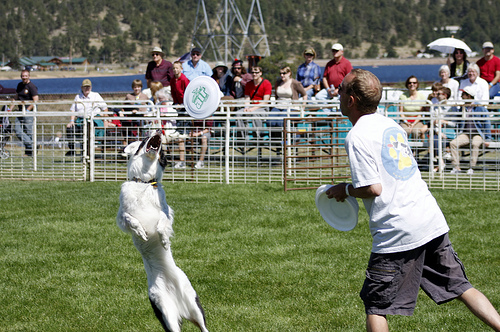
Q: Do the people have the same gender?
A: No, they are both male and female.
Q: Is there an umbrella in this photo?
A: Yes, there is an umbrella.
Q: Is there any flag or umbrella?
A: Yes, there is an umbrella.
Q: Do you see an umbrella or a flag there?
A: Yes, there is an umbrella.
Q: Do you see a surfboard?
A: No, there are no surfboards.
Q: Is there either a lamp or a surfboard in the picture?
A: No, there are no surfboards or lamps.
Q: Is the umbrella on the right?
A: Yes, the umbrella is on the right of the image.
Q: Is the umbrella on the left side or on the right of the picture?
A: The umbrella is on the right of the image.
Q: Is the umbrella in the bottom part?
A: No, the umbrella is in the top of the image.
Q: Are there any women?
A: Yes, there is a woman.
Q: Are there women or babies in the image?
A: Yes, there is a woman.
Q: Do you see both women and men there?
A: Yes, there are both a woman and a man.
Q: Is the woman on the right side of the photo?
A: Yes, the woman is on the right of the image.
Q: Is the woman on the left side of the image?
A: No, the woman is on the right of the image.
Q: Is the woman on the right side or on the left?
A: The woman is on the right of the image.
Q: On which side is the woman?
A: The woman is on the right of the image.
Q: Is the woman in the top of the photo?
A: Yes, the woman is in the top of the image.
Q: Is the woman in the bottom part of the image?
A: No, the woman is in the top of the image.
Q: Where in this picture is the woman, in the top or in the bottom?
A: The woman is in the top of the image.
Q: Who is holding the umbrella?
A: The woman is holding the umbrella.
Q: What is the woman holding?
A: The woman is holding the umbrella.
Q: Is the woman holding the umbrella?
A: Yes, the woman is holding the umbrella.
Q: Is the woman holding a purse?
A: No, the woman is holding the umbrella.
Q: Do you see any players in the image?
A: No, there are no players.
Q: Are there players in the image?
A: No, there are no players.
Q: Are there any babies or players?
A: No, there are no players or babies.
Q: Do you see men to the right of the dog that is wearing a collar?
A: Yes, there is a man to the right of the dog.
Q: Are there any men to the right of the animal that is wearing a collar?
A: Yes, there is a man to the right of the dog.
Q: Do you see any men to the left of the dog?
A: No, the man is to the right of the dog.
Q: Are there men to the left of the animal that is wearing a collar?
A: No, the man is to the right of the dog.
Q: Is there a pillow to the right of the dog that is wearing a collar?
A: No, there is a man to the right of the dog.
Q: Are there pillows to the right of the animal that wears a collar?
A: No, there is a man to the right of the dog.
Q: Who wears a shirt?
A: The man wears a shirt.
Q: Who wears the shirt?
A: The man wears a shirt.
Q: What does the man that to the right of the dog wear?
A: The man wears a shirt.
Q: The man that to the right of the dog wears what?
A: The man wears a shirt.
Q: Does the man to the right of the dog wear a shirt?
A: Yes, the man wears a shirt.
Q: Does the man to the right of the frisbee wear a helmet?
A: No, the man wears a shirt.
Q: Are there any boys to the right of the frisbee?
A: No, there is a man to the right of the frisbee.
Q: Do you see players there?
A: No, there are no players.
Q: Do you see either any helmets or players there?
A: No, there are no players or helmets.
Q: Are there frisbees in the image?
A: Yes, there is a frisbee.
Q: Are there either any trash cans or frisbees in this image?
A: Yes, there is a frisbee.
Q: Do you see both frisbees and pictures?
A: No, there is a frisbee but no pictures.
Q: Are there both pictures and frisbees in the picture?
A: No, there is a frisbee but no pictures.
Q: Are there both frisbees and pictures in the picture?
A: No, there is a frisbee but no pictures.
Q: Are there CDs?
A: No, there are no cds.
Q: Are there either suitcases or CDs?
A: No, there are no CDs or suitcases.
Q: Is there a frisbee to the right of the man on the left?
A: Yes, there is a frisbee to the right of the man.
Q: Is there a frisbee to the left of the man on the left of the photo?
A: No, the frisbee is to the right of the man.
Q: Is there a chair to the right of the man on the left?
A: No, there is a frisbee to the right of the man.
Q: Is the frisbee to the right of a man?
A: Yes, the frisbee is to the right of a man.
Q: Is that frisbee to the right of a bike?
A: No, the frisbee is to the right of a man.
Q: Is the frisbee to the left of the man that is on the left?
A: No, the frisbee is to the right of the man.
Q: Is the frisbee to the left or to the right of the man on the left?
A: The frisbee is to the right of the man.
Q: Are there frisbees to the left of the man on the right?
A: Yes, there is a frisbee to the left of the man.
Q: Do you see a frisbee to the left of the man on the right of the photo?
A: Yes, there is a frisbee to the left of the man.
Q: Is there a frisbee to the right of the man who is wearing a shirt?
A: No, the frisbee is to the left of the man.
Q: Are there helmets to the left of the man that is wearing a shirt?
A: No, there is a frisbee to the left of the man.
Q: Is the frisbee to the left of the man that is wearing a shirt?
A: Yes, the frisbee is to the left of the man.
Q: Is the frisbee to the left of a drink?
A: No, the frisbee is to the left of the man.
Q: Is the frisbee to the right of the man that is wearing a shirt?
A: No, the frisbee is to the left of the man.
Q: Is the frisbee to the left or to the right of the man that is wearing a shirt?
A: The frisbee is to the left of the man.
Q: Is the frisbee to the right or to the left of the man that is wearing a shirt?
A: The frisbee is to the left of the man.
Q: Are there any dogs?
A: Yes, there is a dog.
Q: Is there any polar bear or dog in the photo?
A: Yes, there is a dog.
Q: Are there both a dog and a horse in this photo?
A: No, there is a dog but no horses.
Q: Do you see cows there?
A: No, there are no cows.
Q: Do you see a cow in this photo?
A: No, there are no cows.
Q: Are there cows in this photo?
A: No, there are no cows.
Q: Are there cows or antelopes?
A: No, there are no cows or antelopes.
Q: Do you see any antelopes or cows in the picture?
A: No, there are no cows or antelopes.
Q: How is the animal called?
A: The animal is a dog.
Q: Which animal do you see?
A: The animal is a dog.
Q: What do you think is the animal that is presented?
A: The animal is a dog.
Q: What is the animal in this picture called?
A: The animal is a dog.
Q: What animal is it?
A: The animal is a dog.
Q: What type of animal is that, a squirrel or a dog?
A: That is a dog.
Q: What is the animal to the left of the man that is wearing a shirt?
A: The animal is a dog.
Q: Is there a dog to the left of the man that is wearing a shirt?
A: Yes, there is a dog to the left of the man.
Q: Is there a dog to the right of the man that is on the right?
A: No, the dog is to the left of the man.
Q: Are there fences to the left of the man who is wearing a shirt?
A: No, there is a dog to the left of the man.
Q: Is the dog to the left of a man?
A: Yes, the dog is to the left of a man.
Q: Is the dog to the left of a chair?
A: No, the dog is to the left of a man.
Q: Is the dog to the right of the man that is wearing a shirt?
A: No, the dog is to the left of the man.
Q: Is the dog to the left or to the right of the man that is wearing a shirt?
A: The dog is to the left of the man.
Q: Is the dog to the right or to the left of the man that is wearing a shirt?
A: The dog is to the left of the man.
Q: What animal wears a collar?
A: The dog wears a collar.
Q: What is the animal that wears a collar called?
A: The animal is a dog.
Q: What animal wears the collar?
A: The animal is a dog.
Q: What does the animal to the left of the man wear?
A: The dog wears a collar.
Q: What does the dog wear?
A: The dog wears a collar.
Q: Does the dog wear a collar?
A: Yes, the dog wears a collar.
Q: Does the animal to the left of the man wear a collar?
A: Yes, the dog wears a collar.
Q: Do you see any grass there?
A: Yes, there is grass.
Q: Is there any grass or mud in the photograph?
A: Yes, there is grass.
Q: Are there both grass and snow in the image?
A: No, there is grass but no snow.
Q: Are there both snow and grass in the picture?
A: No, there is grass but no snow.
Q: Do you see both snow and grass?
A: No, there is grass but no snow.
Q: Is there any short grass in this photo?
A: Yes, there is short grass.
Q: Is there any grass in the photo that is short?
A: Yes, there is grass that is short.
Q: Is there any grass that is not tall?
A: Yes, there is short grass.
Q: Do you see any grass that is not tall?
A: Yes, there is short grass.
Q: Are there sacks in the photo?
A: No, there are no sacks.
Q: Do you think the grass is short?
A: Yes, the grass is short.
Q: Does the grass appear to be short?
A: Yes, the grass is short.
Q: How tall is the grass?
A: The grass is short.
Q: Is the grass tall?
A: No, the grass is short.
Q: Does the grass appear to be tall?
A: No, the grass is short.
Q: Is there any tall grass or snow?
A: No, there is grass but it is short.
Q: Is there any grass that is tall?
A: No, there is grass but it is short.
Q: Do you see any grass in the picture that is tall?
A: No, there is grass but it is short.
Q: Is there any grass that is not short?
A: No, there is grass but it is short.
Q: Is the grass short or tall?
A: The grass is short.